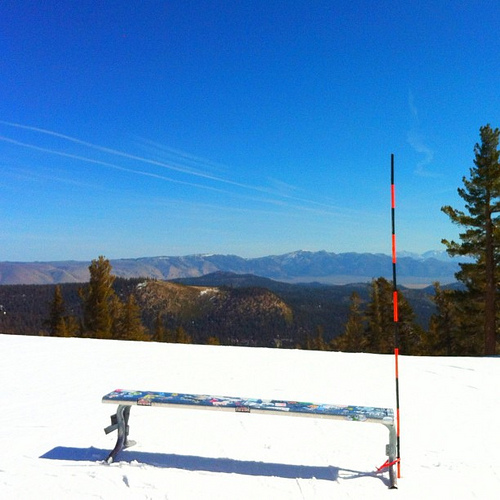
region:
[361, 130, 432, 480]
the pole stick is red and black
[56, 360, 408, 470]
the bench is empty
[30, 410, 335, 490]
shadow of the bench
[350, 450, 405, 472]
the stick is tied to the bench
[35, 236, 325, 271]
mountains in the background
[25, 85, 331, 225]
white lines in the sky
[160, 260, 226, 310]
snow in the distance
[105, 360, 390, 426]
the bench has stickers on it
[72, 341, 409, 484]
the bench is made of metal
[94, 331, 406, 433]
the bench is skinny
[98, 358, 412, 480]
a bench on a snow covered mountain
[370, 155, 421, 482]
a black and orange striped pole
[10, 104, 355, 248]
airplaine contrails in the sky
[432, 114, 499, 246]
an evergreen tree on the side of the mountain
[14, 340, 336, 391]
snow on top of a hill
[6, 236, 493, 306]
mountains in the distance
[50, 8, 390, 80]
bright blue sky with no clouds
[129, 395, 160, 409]
a sticker on a bench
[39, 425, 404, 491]
shadow of a bench on the ground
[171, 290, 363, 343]
trees on the side of the slope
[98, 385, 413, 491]
Bench on the snow.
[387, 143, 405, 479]
Black and red pole attached to bench.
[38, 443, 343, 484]
Shadow from bench on the snow.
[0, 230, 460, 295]
Mountains in the background.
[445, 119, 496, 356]
Tree in the background.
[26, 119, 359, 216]
White streaks in the sky.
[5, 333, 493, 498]
Snow on the ground.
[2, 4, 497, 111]
Bright blue sky above the mountains.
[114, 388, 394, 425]
Stickers on the bench.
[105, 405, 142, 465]
Metal legs on the bench.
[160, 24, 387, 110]
bright blue sky with no clouds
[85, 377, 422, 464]
bench placed on top of snow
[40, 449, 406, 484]
shadow of bench underneath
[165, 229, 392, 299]
mountains in the distance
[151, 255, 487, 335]
green trees on mountain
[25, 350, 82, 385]
white snow covering ground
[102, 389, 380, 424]
stickers on top of bench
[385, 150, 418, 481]
tall red and black pole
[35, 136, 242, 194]
white lines from airpanes in sky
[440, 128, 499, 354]
tall green pine tree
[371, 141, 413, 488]
red and black pole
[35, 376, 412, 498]
multi colored bench with shadow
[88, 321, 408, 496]
bench on snowy mountain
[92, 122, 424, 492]
pole attached to bench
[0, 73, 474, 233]
jet contrails in blue sky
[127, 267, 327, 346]
tree covered mountain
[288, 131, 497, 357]
pine trees going down mountain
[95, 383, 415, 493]
metal bench with colorful seat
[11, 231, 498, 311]
distant mountain range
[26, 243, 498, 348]
pine tree forest